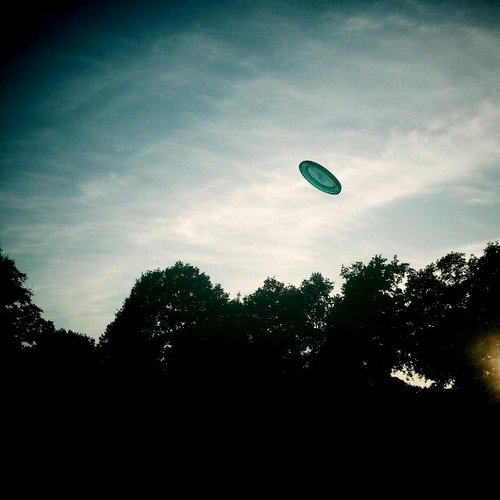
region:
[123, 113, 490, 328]
frisbee flying above tree line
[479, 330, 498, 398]
glimmer of sunlight shining through trees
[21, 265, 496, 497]
trees are green and dense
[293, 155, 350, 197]
frisbee is round and green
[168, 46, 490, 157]
sky is gray and cloudy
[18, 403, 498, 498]
grassy area of park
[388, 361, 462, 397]
small break in tree line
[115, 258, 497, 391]
deciduous trees with leaves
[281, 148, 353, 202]
green frisbee with white cloud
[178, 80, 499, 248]
streak of white cloud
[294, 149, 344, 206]
The frisbee is blue.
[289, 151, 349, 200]
The frisbee is in the air.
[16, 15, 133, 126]
The sky is dark.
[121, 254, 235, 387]
The trees in the background are dark.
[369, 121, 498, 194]
The clouds in the sky are white.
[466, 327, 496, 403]
The sun is shining through the trees.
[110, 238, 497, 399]
There are many trees in the background.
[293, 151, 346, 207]
The frisbee is shaped in a circle.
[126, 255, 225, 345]
The leaves are dark in color.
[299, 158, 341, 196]
a frisbee is in mid air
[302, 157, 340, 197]
the frisbee appears oval in shape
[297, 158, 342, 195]
the frisbee is tilted at an angle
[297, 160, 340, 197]
the frisbee is green in color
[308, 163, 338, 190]
an inner circle is on the frisbee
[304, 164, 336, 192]
the circle is black in color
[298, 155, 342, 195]
the frisbee is circular in shape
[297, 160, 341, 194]
the frisbee is round in shape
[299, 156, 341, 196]
the frisbee is seen from under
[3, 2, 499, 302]
the sky is dark and blue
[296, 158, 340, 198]
a frisbee is in the air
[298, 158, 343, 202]
a frisbee is flying across the air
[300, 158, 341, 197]
a frisbee is in mid flight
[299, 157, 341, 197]
the frisbee is at an angle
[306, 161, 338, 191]
the frisbee has a cirlce inside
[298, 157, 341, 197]
the frisbee has a circular shape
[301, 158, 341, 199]
the frisbee is seen from underneath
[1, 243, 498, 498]
a bunch of trees are under the frisbee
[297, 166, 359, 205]
FRISBEE IN MID AIR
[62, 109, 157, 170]
WHITE CLOUDS AT HIGH ALTITUDE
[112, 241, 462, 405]
OUTLINE OF TREES IN BACKGROUND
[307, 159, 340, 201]
ROUND CIRCLE ON BLUE FRISBEE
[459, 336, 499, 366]
LIGHT SHINING ON TREES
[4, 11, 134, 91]
DARK FADE ON CORNERS OF PHOTO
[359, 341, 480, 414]
LIGHT SHINING THROUGH TREES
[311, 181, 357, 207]
EDGE OF BLUE FRISBEE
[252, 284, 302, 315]
GREEN LEAVES ON TREES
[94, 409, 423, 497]
DARK SURFACE BELOW IN SHADOWS